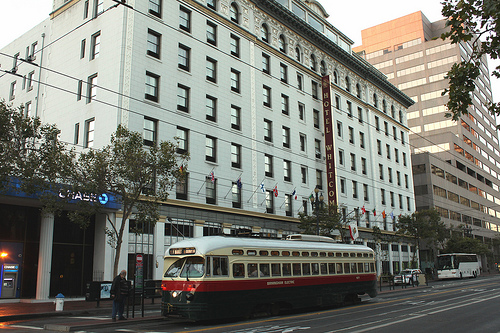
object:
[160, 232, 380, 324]
trolley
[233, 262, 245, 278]
windows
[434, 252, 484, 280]
bus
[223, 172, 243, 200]
flags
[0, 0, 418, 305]
building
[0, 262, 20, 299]
atm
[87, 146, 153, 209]
tree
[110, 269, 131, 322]
man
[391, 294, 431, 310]
lines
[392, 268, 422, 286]
car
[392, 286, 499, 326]
road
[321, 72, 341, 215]
sign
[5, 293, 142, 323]
sidewalk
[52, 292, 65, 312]
hydrant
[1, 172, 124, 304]
bank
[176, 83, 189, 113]
windows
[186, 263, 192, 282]
wipers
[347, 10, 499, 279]
building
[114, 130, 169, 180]
leaves